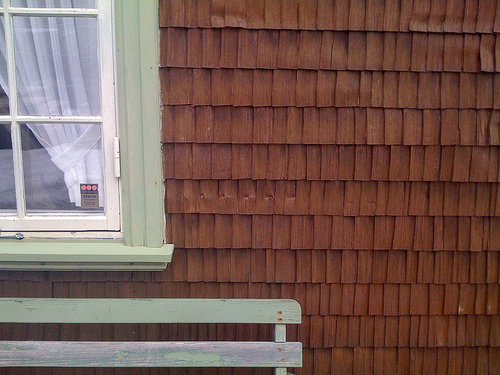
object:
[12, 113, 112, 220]
window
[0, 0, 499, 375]
brown wall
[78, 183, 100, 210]
sign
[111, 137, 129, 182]
hinge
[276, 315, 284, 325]
holes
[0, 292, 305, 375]
bench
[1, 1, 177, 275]
window frame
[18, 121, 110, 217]
glass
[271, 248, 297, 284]
shingle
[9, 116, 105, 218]
pane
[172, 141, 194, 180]
wall blocks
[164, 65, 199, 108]
block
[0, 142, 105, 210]
bed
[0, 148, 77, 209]
spread